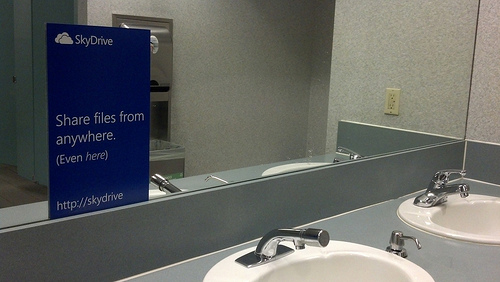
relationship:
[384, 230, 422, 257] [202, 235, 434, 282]
soap dispenser in front of sink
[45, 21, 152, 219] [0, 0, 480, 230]
sign mounted on mirror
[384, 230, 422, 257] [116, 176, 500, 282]
soap dispenser on top of counter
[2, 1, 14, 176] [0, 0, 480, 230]
doorway reflected in mirror